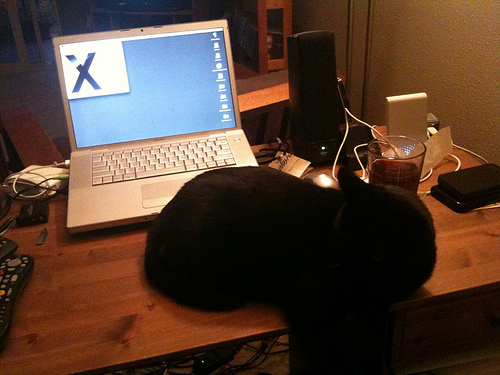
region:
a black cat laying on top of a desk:
[143, 160, 438, 317]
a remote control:
[2, 249, 35, 345]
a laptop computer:
[60, 17, 254, 228]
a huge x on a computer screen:
[66, 47, 107, 94]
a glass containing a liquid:
[366, 135, 428, 191]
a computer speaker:
[287, 30, 344, 164]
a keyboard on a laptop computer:
[91, 140, 231, 179]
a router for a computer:
[429, 164, 498, 214]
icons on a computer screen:
[211, 36, 233, 123]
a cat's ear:
[335, 160, 364, 194]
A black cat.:
[139, 154, 444, 361]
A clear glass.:
[363, 127, 433, 225]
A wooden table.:
[5, 130, 498, 374]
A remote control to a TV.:
[2, 252, 37, 357]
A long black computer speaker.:
[291, 24, 360, 179]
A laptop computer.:
[46, 14, 280, 234]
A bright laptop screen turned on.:
[49, 29, 266, 151]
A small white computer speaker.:
[379, 88, 441, 170]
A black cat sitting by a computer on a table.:
[36, 151, 498, 371]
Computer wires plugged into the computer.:
[6, 159, 79, 195]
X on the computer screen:
[56, 42, 139, 102]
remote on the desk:
[8, 246, 36, 346]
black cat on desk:
[175, 168, 438, 313]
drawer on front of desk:
[385, 287, 494, 352]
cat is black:
[170, 181, 435, 280]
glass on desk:
[355, 126, 441, 208]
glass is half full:
[369, 130, 449, 199]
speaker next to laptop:
[256, 18, 348, 154]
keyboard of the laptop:
[60, 136, 283, 182]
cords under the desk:
[130, 342, 337, 372]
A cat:
[128, 127, 378, 331]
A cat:
[183, 197, 310, 366]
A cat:
[200, 237, 297, 329]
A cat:
[252, 88, 337, 348]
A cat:
[237, 160, 359, 297]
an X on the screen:
[69, 43, 125, 95]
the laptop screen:
[44, 30, 245, 135]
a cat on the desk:
[112, 158, 451, 340]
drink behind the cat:
[356, 127, 428, 209]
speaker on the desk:
[288, 19, 350, 167]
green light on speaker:
[315, 140, 333, 152]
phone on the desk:
[433, 154, 498, 213]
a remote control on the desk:
[0, 243, 39, 347]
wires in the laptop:
[13, 157, 68, 199]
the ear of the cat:
[332, 162, 365, 197]